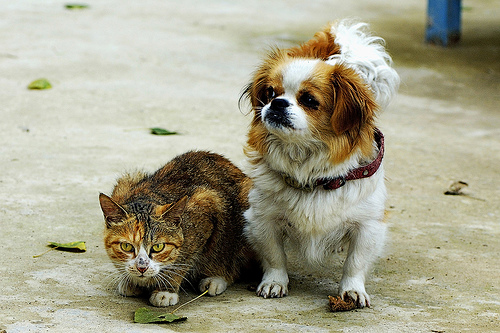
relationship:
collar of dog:
[274, 121, 387, 192] [252, 47, 394, 307]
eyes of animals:
[116, 236, 171, 256] [97, 149, 265, 304]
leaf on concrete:
[137, 122, 185, 143] [0, 0, 499, 333]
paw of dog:
[248, 267, 294, 307] [252, 47, 394, 307]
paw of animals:
[201, 266, 228, 296] [97, 149, 265, 304]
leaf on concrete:
[313, 291, 357, 304] [0, 0, 499, 333]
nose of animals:
[134, 268, 146, 274] [97, 149, 265, 304]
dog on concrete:
[252, 47, 394, 307] [0, 0, 499, 333]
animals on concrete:
[97, 149, 265, 304] [0, 0, 499, 333]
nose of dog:
[267, 94, 292, 124] [252, 47, 394, 307]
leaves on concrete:
[37, 54, 177, 153] [0, 0, 499, 333]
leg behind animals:
[424, 0, 463, 45] [115, 58, 404, 283]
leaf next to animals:
[134, 310, 201, 328] [97, 149, 265, 304]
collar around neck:
[274, 121, 387, 192] [237, 132, 378, 185]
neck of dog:
[237, 132, 378, 185] [252, 47, 394, 307]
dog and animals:
[252, 47, 394, 307] [97, 149, 265, 304]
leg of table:
[424, 9, 457, 43] [415, 7, 491, 51]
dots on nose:
[136, 256, 149, 262] [134, 268, 146, 274]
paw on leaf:
[330, 284, 358, 306] [313, 291, 357, 304]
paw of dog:
[330, 284, 358, 306] [252, 47, 394, 307]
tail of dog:
[331, 20, 412, 100] [252, 47, 394, 307]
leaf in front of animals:
[134, 310, 201, 328] [97, 149, 265, 304]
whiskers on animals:
[106, 259, 190, 299] [97, 149, 265, 304]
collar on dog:
[274, 121, 387, 192] [252, 47, 394, 307]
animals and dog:
[97, 149, 265, 304] [252, 47, 394, 307]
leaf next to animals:
[137, 122, 185, 143] [97, 149, 265, 304]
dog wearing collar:
[252, 47, 394, 307] [274, 121, 387, 192]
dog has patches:
[252, 47, 394, 307] [299, 67, 365, 142]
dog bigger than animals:
[252, 47, 394, 307] [97, 149, 265, 304]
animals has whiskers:
[97, 149, 265, 304] [106, 259, 190, 299]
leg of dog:
[251, 207, 289, 307] [252, 47, 394, 307]